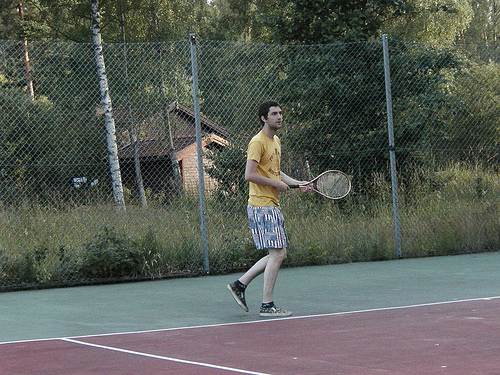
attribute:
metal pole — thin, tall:
[184, 30, 219, 272]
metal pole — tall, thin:
[374, 28, 409, 261]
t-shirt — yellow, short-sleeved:
[246, 135, 283, 206]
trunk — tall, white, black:
[97, 76, 123, 175]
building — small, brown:
[117, 135, 231, 203]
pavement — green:
[3, 247, 498, 342]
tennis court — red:
[6, 259, 498, 372]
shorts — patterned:
[247, 198, 289, 255]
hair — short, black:
[261, 100, 270, 107]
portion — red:
[3, 292, 485, 373]